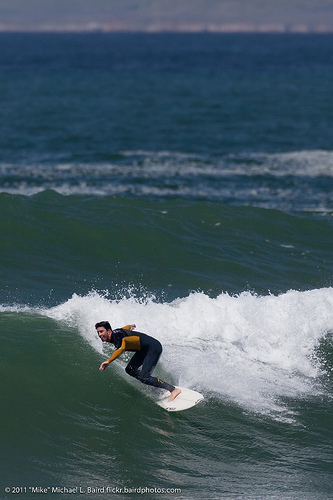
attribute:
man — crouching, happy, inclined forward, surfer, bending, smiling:
[93, 323, 179, 401]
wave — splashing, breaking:
[18, 308, 331, 412]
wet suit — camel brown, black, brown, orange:
[112, 331, 173, 390]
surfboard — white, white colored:
[147, 378, 203, 413]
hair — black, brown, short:
[93, 321, 112, 329]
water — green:
[1, 32, 332, 499]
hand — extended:
[98, 361, 109, 373]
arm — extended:
[104, 338, 127, 367]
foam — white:
[189, 348, 317, 418]